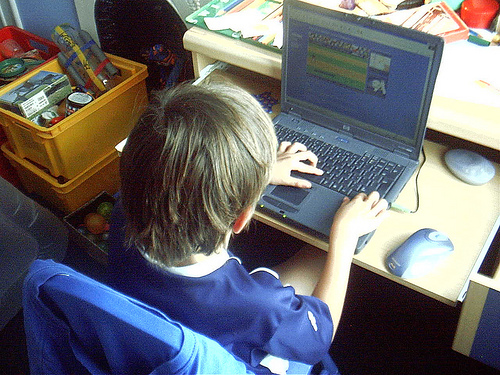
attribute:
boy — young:
[93, 77, 388, 372]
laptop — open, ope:
[233, 1, 442, 261]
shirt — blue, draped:
[9, 257, 238, 369]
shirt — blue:
[102, 197, 333, 366]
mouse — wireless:
[381, 221, 463, 279]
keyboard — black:
[267, 121, 411, 243]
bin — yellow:
[3, 49, 159, 179]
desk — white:
[148, 2, 496, 313]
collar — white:
[116, 210, 236, 280]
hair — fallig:
[101, 81, 271, 270]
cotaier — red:
[451, 3, 500, 24]